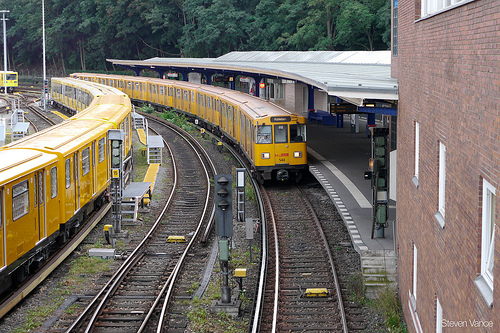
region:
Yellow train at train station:
[170, 60, 355, 194]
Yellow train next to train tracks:
[127, 79, 371, 214]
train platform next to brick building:
[230, 172, 472, 332]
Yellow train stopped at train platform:
[184, 70, 364, 212]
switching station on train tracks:
[65, 167, 335, 317]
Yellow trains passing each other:
[38, 41, 333, 191]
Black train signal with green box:
[202, 163, 244, 316]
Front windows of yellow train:
[250, 105, 315, 197]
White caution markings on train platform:
[304, 77, 406, 269]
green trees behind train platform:
[44, 0, 401, 94]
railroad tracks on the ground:
[57, 191, 364, 331]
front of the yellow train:
[250, 112, 310, 189]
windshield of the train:
[252, 120, 307, 146]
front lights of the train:
[259, 150, 304, 160]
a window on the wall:
[407, 118, 424, 188]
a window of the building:
[430, 137, 453, 232]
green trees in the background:
[6, 0, 391, 75]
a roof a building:
[105, 45, 391, 97]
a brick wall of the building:
[390, 0, 499, 331]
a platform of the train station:
[309, 117, 391, 247]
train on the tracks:
[68, 70, 313, 192]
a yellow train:
[67, 69, 312, 193]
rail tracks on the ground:
[66, 188, 353, 331]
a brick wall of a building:
[390, 1, 495, 322]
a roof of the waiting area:
[102, 46, 394, 91]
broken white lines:
[308, 164, 369, 253]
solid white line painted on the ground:
[310, 142, 372, 208]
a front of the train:
[251, 113, 309, 169]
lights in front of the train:
[258, 149, 303, 160]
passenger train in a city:
[29, 25, 389, 320]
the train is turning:
[83, 64, 310, 189]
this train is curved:
[14, 65, 153, 244]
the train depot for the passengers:
[154, 41, 414, 227]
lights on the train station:
[219, 77, 271, 96]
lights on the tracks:
[196, 158, 257, 313]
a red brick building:
[386, 6, 487, 326]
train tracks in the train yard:
[148, 113, 224, 318]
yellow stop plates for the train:
[156, 221, 337, 307]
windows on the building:
[392, 127, 497, 313]